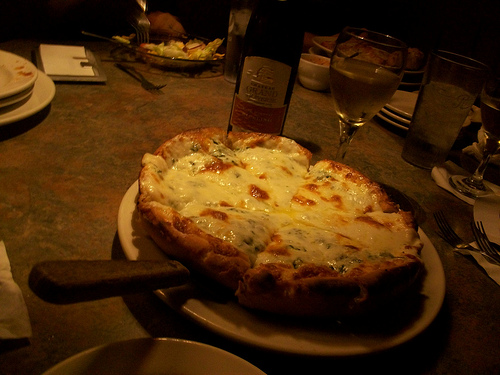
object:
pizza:
[141, 132, 425, 317]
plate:
[113, 143, 446, 356]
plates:
[1, 49, 59, 129]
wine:
[333, 59, 401, 120]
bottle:
[225, 2, 305, 143]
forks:
[470, 221, 500, 268]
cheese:
[162, 145, 398, 266]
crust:
[230, 248, 428, 322]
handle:
[27, 258, 187, 307]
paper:
[44, 47, 95, 76]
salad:
[140, 32, 225, 59]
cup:
[402, 50, 488, 171]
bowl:
[43, 336, 270, 374]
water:
[410, 80, 470, 166]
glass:
[326, 25, 409, 165]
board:
[34, 41, 107, 86]